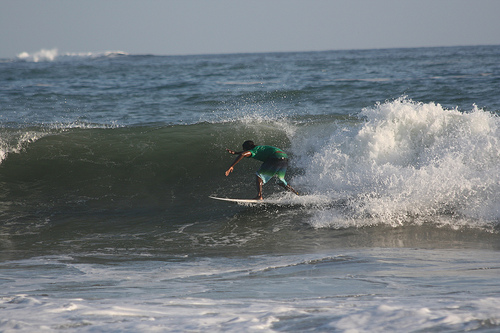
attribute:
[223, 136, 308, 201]
person — a man, a surfer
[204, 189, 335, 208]
surfboard — partially submerged, white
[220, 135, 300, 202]
man — tan, surfing, young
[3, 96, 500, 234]
wave — foamy, high, moderate sized, crashing, white, foaming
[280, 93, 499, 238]
foam — white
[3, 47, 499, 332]
water — blue, turbulent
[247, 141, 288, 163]
shirt — green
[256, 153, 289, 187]
shorts — green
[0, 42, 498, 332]
ocean — massive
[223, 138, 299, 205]
boy — bending forward, young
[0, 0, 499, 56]
sky — overcast, blue, gray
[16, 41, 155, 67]
waves — in background, foaming up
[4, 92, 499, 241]
ocean wave — growing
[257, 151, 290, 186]
swimming trunks — faded